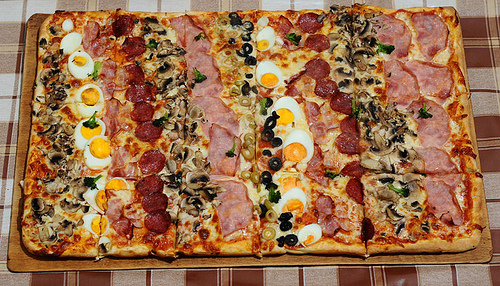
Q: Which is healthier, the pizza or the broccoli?
A: The broccoli is healthier than the pizza.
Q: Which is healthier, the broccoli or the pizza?
A: The broccoli is healthier than the pizza.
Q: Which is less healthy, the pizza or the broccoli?
A: The pizza is less healthy than the broccoli.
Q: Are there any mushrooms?
A: Yes, there are mushrooms.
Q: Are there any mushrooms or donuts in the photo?
A: Yes, there are mushrooms.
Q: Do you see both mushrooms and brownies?
A: No, there are mushrooms but no brownies.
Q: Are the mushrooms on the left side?
A: Yes, the mushrooms are on the left of the image.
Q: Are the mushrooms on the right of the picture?
A: No, the mushrooms are on the left of the image.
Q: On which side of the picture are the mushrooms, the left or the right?
A: The mushrooms are on the left of the image.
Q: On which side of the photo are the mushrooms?
A: The mushrooms are on the left of the image.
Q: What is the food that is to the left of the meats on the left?
A: The food is mushrooms.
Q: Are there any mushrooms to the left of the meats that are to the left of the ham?
A: Yes, there are mushrooms to the left of the meats.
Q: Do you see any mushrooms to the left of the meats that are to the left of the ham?
A: Yes, there are mushrooms to the left of the meats.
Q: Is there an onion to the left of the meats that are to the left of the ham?
A: No, there are mushrooms to the left of the meats.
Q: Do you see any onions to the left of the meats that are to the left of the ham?
A: No, there are mushrooms to the left of the meats.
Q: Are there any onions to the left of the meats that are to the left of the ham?
A: No, there are mushrooms to the left of the meats.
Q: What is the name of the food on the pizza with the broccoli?
A: The food is mushrooms.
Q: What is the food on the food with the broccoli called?
A: The food is mushrooms.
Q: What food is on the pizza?
A: The food is mushrooms.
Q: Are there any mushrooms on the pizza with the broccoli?
A: Yes, there are mushrooms on the pizza.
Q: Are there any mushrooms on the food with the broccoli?
A: Yes, there are mushrooms on the pizza.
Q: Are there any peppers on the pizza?
A: No, there are mushrooms on the pizza.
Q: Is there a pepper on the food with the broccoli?
A: No, there are mushrooms on the pizza.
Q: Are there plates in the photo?
A: No, there are no plates.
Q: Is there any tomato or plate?
A: No, there are no plates or tomatoes.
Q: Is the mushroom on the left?
A: Yes, the mushroom is on the left of the image.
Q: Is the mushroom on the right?
A: No, the mushroom is on the left of the image.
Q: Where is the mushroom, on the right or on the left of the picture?
A: The mushroom is on the left of the image.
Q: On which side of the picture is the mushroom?
A: The mushroom is on the left of the image.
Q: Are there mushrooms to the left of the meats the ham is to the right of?
A: Yes, there is a mushroom to the left of the meats.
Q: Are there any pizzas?
A: Yes, there is a pizza.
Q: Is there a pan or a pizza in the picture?
A: Yes, there is a pizza.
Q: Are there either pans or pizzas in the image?
A: Yes, there is a pizza.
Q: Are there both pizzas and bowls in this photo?
A: No, there is a pizza but no bowls.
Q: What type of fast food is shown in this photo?
A: The fast food is a pizza.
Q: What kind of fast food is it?
A: The food is a pizza.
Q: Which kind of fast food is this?
A: This is a pizza.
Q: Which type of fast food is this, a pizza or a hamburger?
A: This is a pizza.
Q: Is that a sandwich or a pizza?
A: That is a pizza.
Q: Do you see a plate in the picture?
A: No, there are no plates.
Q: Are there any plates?
A: No, there are no plates.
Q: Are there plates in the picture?
A: No, there are no plates.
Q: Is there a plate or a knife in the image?
A: No, there are no plates or knives.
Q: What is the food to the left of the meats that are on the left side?
A: The food is an egg.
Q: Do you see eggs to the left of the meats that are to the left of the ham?
A: Yes, there is an egg to the left of the meats.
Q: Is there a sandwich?
A: No, there are no sandwiches.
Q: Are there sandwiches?
A: No, there are no sandwiches.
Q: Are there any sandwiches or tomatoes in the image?
A: No, there are no sandwiches or tomatoes.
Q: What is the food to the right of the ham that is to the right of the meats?
A: The food is eggs.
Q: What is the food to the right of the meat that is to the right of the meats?
A: The food is eggs.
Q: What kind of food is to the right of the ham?
A: The food is eggs.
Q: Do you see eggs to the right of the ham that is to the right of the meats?
A: Yes, there are eggs to the right of the ham.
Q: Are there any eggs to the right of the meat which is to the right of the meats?
A: Yes, there are eggs to the right of the ham.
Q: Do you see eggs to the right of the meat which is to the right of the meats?
A: Yes, there are eggs to the right of the ham.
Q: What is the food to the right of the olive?
A: The food is eggs.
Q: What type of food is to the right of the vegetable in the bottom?
A: The food is eggs.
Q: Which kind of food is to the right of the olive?
A: The food is eggs.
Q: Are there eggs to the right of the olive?
A: Yes, there are eggs to the right of the olive.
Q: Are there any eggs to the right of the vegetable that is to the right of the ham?
A: Yes, there are eggs to the right of the olive.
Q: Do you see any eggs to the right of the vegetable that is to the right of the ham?
A: Yes, there are eggs to the right of the olive.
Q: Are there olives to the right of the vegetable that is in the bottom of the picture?
A: No, there are eggs to the right of the olive.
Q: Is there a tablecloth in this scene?
A: Yes, there is a tablecloth.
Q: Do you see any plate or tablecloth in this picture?
A: Yes, there is a tablecloth.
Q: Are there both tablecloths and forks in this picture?
A: No, there is a tablecloth but no forks.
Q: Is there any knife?
A: No, there are no knives.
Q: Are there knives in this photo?
A: No, there are no knives.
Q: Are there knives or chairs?
A: No, there are no knives or chairs.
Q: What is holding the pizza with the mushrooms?
A: The table cloth is holding the pizza.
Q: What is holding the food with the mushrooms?
A: The table cloth is holding the pizza.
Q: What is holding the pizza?
A: The table cloth is holding the pizza.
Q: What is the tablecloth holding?
A: The tablecloth is holding the pizza.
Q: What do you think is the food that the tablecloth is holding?
A: The food is a pizza.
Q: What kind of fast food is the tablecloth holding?
A: The tablecloth is holding the pizza.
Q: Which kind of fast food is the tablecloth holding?
A: The tablecloth is holding the pizza.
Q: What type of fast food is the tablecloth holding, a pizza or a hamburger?
A: The tablecloth is holding a pizza.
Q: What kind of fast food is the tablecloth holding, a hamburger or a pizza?
A: The tablecloth is holding a pizza.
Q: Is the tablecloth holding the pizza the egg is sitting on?
A: Yes, the tablecloth is holding the pizza.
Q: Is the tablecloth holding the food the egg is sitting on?
A: Yes, the tablecloth is holding the pizza.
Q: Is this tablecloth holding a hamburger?
A: No, the tablecloth is holding the pizza.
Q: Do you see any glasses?
A: No, there are no glasses.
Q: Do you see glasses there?
A: No, there are no glasses.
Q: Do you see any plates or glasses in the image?
A: No, there are no glasses or plates.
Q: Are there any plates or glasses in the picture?
A: No, there are no glasses or plates.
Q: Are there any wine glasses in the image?
A: No, there are no wine glasses.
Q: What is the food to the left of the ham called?
A: The food is meats.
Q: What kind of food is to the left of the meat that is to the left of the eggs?
A: The food is meats.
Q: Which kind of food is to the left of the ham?
A: The food is meats.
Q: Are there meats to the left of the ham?
A: Yes, there are meats to the left of the ham.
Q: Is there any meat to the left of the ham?
A: Yes, there are meats to the left of the ham.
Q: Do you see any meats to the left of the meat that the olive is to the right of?
A: Yes, there are meats to the left of the ham.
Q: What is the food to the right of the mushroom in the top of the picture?
A: The food is meats.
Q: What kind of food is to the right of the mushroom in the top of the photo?
A: The food is meats.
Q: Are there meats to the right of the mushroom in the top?
A: Yes, there are meats to the right of the mushroom.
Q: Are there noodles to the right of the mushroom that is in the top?
A: No, there are meats to the right of the mushroom.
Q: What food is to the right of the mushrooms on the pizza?
A: The food is meats.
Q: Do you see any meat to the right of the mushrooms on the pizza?
A: Yes, there are meats to the right of the mushrooms.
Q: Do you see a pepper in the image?
A: No, there are no peppers.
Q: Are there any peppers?
A: No, there are no peppers.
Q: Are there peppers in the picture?
A: No, there are no peppers.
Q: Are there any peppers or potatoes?
A: No, there are no peppers or potatoes.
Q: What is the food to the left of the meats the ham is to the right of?
A: The food is an egg.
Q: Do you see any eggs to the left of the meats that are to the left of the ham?
A: Yes, there is an egg to the left of the meats.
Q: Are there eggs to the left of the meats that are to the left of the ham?
A: Yes, there is an egg to the left of the meats.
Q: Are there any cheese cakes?
A: No, there are no cheese cakes.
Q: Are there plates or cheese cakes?
A: No, there are no cheese cakes or plates.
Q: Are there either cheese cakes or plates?
A: No, there are no cheese cakes or plates.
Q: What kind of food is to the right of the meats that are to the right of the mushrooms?
A: The food is an egg.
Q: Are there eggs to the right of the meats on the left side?
A: Yes, there is an egg to the right of the meats.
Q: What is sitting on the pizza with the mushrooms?
A: The egg is sitting on the pizza.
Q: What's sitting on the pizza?
A: The egg is sitting on the pizza.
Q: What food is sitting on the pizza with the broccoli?
A: The food is an egg.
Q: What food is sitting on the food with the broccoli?
A: The food is an egg.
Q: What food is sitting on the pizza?
A: The food is an egg.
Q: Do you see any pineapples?
A: No, there are no pineapples.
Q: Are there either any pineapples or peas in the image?
A: No, there are no pineapples or peas.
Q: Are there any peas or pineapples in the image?
A: No, there are no pineapples or peas.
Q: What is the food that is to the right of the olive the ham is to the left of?
A: The food is an egg.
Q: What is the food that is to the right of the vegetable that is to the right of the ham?
A: The food is an egg.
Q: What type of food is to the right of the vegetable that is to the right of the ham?
A: The food is an egg.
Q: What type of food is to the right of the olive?
A: The food is an egg.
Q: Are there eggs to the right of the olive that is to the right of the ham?
A: Yes, there is an egg to the right of the olive.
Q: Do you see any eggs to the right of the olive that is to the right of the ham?
A: Yes, there is an egg to the right of the olive.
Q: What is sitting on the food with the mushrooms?
A: The egg is sitting on the pizza.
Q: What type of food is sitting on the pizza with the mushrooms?
A: The food is an egg.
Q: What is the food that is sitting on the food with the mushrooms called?
A: The food is an egg.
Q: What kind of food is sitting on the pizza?
A: The food is an egg.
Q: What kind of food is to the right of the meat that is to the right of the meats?
A: The food is an egg.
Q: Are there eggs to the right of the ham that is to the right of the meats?
A: Yes, there is an egg to the right of the ham.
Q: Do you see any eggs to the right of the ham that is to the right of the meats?
A: Yes, there is an egg to the right of the ham.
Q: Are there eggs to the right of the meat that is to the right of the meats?
A: Yes, there is an egg to the right of the ham.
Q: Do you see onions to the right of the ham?
A: No, there is an egg to the right of the ham.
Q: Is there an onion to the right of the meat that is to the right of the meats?
A: No, there is an egg to the right of the ham.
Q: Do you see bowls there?
A: No, there are no bowls.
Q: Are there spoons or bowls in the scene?
A: No, there are no bowls or spoons.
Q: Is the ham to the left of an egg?
A: Yes, the ham is to the left of an egg.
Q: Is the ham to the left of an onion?
A: No, the ham is to the left of an egg.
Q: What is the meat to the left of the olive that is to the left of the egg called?
A: The meat is ham.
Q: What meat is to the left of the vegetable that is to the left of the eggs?
A: The meat is ham.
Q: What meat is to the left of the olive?
A: The meat is ham.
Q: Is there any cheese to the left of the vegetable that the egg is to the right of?
A: No, there is ham to the left of the olive.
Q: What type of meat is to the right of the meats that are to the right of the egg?
A: The meat is ham.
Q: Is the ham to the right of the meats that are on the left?
A: Yes, the ham is to the right of the meats.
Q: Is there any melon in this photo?
A: No, there are no melons.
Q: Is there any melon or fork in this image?
A: No, there are no melons or forks.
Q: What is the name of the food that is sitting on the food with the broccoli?
A: The food is an egg.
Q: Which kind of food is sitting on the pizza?
A: The food is an egg.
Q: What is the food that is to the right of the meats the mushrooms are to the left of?
A: The food is an egg.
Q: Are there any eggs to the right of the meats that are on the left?
A: Yes, there is an egg to the right of the meats.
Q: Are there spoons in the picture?
A: No, there are no spoons.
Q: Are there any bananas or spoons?
A: No, there are no spoons or bananas.